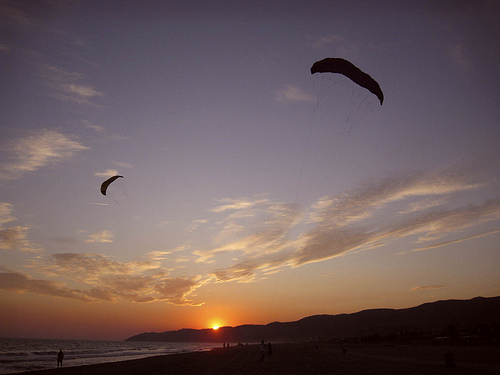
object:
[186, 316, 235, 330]
sunset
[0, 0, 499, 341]
sky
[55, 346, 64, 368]
person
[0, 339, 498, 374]
beach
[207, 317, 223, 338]
sun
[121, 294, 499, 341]
mountains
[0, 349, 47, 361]
waves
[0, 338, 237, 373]
water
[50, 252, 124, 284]
cloud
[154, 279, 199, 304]
cloud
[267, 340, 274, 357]
person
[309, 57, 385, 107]
kite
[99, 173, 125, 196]
parachute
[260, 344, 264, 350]
vest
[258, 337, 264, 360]
man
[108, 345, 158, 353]
waves